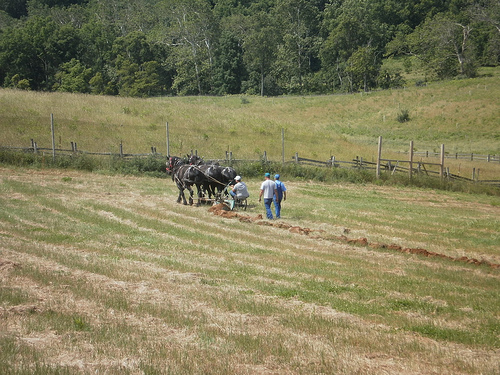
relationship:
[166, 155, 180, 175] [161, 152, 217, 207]
head on horse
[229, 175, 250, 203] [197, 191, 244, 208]
man in cart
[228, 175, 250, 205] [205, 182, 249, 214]
man sitting on cart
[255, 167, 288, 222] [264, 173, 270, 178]
men wearing hat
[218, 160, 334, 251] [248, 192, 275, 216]
man wearing short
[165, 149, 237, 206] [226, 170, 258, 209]
horses pulling man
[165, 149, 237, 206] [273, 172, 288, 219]
horses working to man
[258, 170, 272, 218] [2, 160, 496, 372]
man in field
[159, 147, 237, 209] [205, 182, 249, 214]
horses pulling cart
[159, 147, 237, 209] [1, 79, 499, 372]
horses in grass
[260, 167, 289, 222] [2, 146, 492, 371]
two men walking along grass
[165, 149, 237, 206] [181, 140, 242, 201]
horses pulling cart